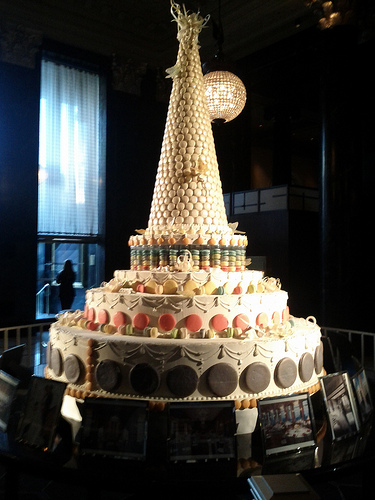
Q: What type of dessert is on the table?
A: A cake.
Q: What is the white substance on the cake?
A: Frosting.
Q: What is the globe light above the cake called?
A: A disco ball.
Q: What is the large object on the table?
A: A cake.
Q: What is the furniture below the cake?
A: A table.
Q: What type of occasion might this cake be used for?
A: A wedding.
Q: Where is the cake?
A: In the photo.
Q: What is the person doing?
A: Standing.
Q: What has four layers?
A: The cake.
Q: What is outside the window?
A: Light.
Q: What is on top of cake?
A: Tower decoration.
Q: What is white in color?
A: The cake.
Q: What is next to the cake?
A: Photos.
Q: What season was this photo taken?
A: Summer.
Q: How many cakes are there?
A: One.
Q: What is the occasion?
A: A wedding.